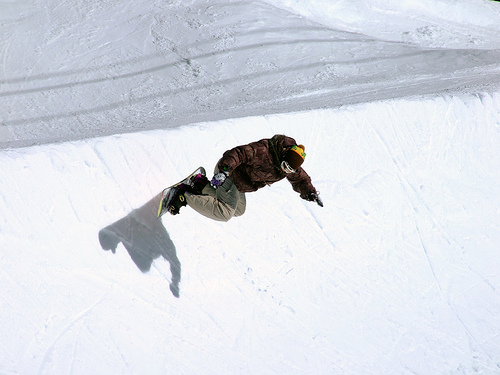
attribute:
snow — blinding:
[264, 270, 490, 364]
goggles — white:
[274, 156, 301, 181]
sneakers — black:
[166, 181, 206, 232]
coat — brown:
[217, 132, 319, 201]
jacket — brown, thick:
[220, 133, 318, 208]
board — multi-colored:
[151, 161, 209, 219]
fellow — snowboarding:
[170, 130, 323, 230]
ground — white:
[1, 1, 498, 373]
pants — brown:
[189, 176, 245, 221]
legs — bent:
[188, 166, 248, 223]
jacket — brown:
[217, 132, 317, 191]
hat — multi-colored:
[278, 137, 310, 177]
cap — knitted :
[287, 140, 307, 172]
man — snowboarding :
[159, 131, 322, 221]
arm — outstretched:
[284, 162, 316, 197]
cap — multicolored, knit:
[284, 132, 309, 177]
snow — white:
[3, 2, 499, 372]